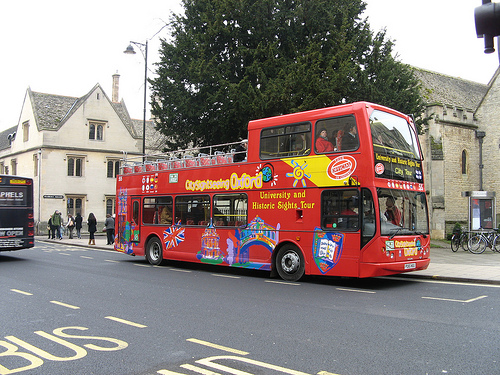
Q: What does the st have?
A: A bus lanes.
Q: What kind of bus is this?
A: Tourist bus.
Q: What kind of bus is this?
A: Double decker bus.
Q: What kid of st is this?
A: A paved city street.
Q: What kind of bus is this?
A: Double decker.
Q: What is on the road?
A: Bus.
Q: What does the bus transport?
A: Passengers.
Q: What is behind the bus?
A: Tree.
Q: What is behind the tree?
A: Building.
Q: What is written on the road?
A: Bus.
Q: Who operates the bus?
A: Driver.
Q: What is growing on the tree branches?
A: Leaves.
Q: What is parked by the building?
A: Bicycles.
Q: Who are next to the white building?
A: The people.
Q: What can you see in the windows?
A: Passagers.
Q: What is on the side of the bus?
A: Advertisements.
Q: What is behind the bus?
A: A group of people.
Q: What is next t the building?
A: Bikecycles.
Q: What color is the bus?
A: Red.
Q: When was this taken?
A: During the day.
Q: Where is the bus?
A: Parked near the curb.